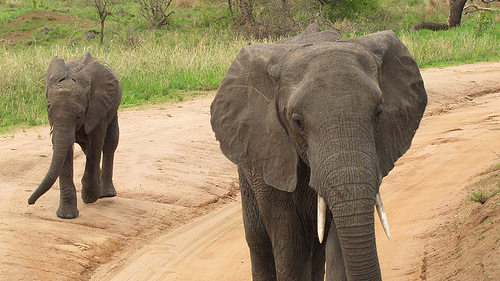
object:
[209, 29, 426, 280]
elephant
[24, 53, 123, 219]
elephant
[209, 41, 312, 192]
right ear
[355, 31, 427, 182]
left ear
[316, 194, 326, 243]
tusk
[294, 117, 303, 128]
eye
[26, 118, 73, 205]
trunk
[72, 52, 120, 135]
left ear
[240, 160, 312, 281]
front leg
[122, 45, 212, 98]
grass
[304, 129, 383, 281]
trunk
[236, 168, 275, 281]
leg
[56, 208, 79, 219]
foot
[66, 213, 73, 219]
toe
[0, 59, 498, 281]
pathway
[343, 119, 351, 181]
line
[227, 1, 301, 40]
bush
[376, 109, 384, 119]
left eye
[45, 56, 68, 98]
right ear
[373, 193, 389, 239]
left tusk